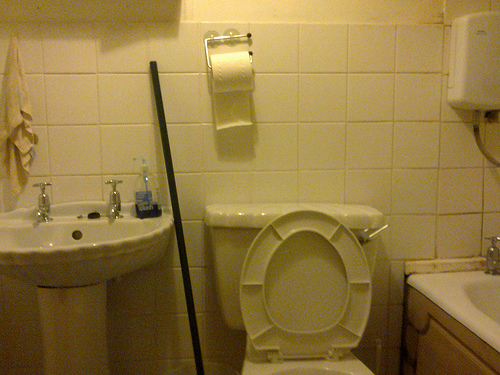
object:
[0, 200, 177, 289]
sink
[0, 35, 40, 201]
towel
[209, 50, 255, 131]
toilet paper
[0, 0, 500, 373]
wall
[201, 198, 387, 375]
toilet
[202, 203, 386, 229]
lid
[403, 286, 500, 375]
bathtub frame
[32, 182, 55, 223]
faucet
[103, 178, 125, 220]
faucet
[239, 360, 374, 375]
seat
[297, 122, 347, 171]
tile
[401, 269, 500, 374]
bathtub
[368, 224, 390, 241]
lever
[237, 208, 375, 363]
lid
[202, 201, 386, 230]
top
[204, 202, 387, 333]
tank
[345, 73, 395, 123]
tile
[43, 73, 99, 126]
tile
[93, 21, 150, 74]
tile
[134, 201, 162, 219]
soap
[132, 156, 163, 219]
bottle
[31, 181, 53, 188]
knob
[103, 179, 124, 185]
knob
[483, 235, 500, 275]
faucet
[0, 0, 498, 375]
bathroom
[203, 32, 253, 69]
paper holder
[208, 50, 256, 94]
roll